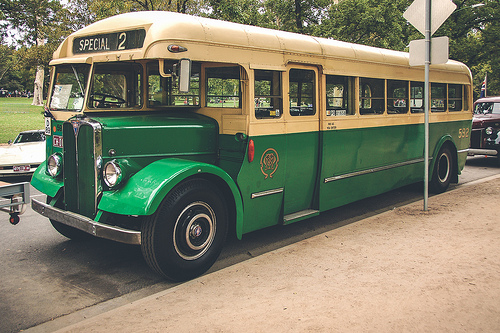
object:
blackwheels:
[134, 180, 237, 284]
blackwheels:
[432, 144, 457, 194]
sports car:
[0, 128, 50, 182]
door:
[280, 61, 325, 223]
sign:
[400, 0, 461, 37]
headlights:
[45, 149, 65, 182]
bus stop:
[41, 173, 499, 333]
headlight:
[102, 160, 124, 187]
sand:
[368, 246, 500, 314]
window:
[284, 62, 324, 119]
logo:
[257, 147, 280, 180]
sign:
[405, 35, 453, 70]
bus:
[29, 6, 476, 282]